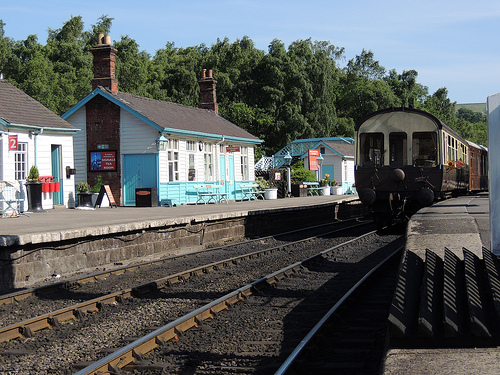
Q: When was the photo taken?
A: Daytime.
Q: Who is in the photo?
A: Nobody.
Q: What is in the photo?
A: Trains.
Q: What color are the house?
A: White.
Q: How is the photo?
A: Clear.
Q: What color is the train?
A: Black.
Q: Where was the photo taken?
A: At the train station.